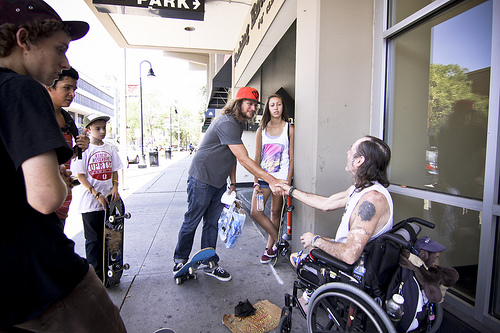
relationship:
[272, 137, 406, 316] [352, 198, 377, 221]
man has tattoo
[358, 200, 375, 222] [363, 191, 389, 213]
tattoo on shoulder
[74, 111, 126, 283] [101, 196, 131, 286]
boy on skateboard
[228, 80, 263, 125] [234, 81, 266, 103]
head in cap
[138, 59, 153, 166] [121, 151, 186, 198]
street light at curb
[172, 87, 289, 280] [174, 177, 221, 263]
man wearing jeans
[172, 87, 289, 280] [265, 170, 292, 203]
man shaking hands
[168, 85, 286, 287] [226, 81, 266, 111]
boy wearing hat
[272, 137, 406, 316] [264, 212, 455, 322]
man in wheel chair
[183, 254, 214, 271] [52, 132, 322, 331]
wheels off ground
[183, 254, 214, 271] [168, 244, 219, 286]
wheels on skateboard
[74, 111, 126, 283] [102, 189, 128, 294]
boy holding skateboard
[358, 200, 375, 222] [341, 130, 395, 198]
tattoo on man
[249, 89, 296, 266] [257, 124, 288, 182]
girl wearing top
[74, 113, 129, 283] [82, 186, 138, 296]
boy holding skateboard